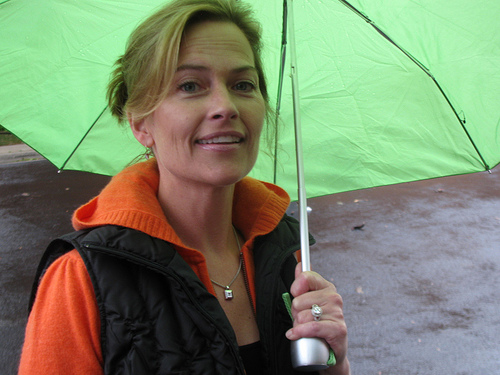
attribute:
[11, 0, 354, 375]
woman — standing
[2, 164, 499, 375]
street — paved, wet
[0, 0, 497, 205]
umbrella — green, mint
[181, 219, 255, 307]
necklace — silver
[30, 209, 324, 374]
vest — black, padded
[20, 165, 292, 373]
sweater — orange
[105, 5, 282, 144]
hair — up, blonde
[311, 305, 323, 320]
ring — diamond, sparkling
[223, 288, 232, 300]
pendant — square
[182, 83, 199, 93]
eye — blue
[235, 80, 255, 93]
eye — blue